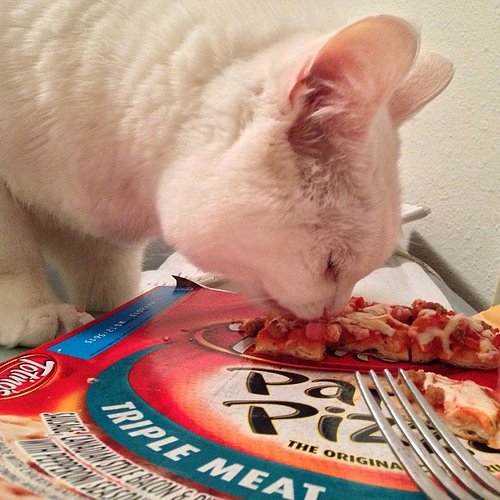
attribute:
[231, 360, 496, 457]
writing — black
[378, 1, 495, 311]
wall — clean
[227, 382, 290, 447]
letter — Black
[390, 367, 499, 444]
pizza — triple-meat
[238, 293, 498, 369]
pizza — triple-meat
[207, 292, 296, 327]
whiskers — white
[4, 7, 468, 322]
cat — white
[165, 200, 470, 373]
party pizza — meat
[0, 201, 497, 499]
box — cardboard, pizza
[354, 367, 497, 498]
fork — silver, metal, dinner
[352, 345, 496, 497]
fork — metallic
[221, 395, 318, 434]
letter — Black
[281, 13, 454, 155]
ears — big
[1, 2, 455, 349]
cat — white, adult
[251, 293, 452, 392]
slice — pizza